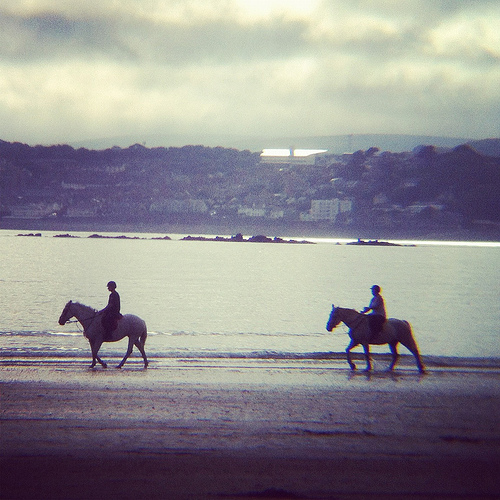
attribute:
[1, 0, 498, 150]
sky — cloudy, grey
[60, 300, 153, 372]
horse — white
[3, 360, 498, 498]
beach — sandy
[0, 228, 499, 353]
water — calm, reflective